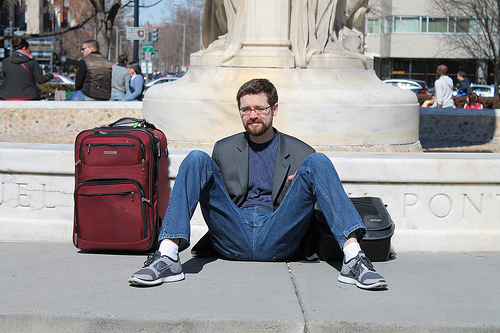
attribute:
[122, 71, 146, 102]
shirt — blue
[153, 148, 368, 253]
jeans — blue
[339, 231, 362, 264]
sock — white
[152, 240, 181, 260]
sock — white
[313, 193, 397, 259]
suit case — black, small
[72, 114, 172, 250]
suitcase — large, red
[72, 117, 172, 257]
luggage — red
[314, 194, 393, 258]
luggage — black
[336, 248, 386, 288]
shoe — gray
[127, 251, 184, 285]
shoe — gray